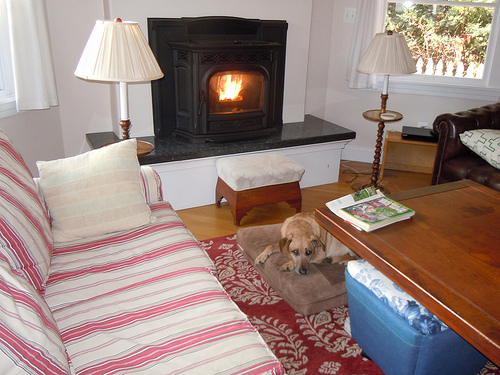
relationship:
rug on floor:
[198, 233, 383, 373] [174, 159, 434, 374]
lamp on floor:
[352, 30, 418, 195] [176, 157, 498, 374]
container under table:
[342, 257, 488, 374] [309, 177, 499, 369]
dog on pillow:
[254, 210, 331, 276] [237, 222, 346, 316]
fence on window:
[425, 51, 480, 73] [380, 2, 495, 91]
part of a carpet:
[278, 305, 301, 349] [237, 266, 344, 355]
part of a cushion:
[103, 273, 176, 341] [7, 94, 259, 374]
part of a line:
[90, 227, 130, 266] [119, 302, 169, 324]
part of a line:
[416, 278, 470, 302] [375, 233, 497, 328]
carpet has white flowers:
[196, 227, 498, 373] [197, 230, 373, 373]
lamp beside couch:
[72, 5, 195, 185] [2, 132, 216, 345]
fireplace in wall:
[140, 12, 291, 140] [0, 0, 499, 178]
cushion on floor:
[232, 224, 356, 326] [197, 204, 348, 323]